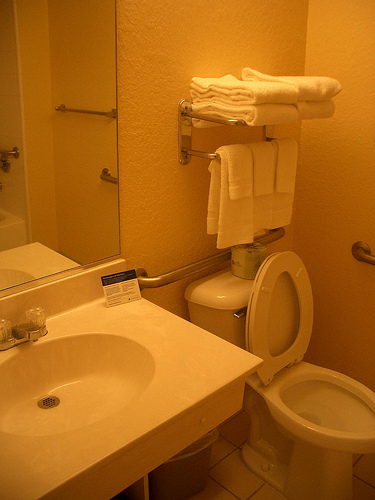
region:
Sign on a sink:
[97, 266, 146, 310]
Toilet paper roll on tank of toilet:
[230, 241, 266, 279]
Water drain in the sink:
[35, 395, 60, 409]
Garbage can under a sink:
[149, 427, 224, 497]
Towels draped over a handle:
[205, 137, 297, 246]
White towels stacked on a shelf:
[190, 65, 339, 122]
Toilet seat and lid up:
[247, 248, 315, 381]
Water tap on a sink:
[0, 306, 50, 350]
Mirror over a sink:
[0, 0, 121, 289]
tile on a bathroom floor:
[184, 406, 370, 499]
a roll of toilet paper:
[224, 233, 262, 286]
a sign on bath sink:
[80, 258, 154, 316]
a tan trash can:
[155, 425, 226, 499]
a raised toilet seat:
[249, 250, 332, 410]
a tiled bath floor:
[187, 447, 262, 498]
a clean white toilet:
[190, 227, 372, 498]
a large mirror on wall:
[2, 0, 162, 270]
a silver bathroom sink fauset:
[0, 294, 77, 349]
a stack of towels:
[173, 49, 348, 141]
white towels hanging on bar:
[159, 140, 350, 253]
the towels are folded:
[200, 76, 358, 146]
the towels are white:
[198, 67, 344, 117]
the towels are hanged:
[215, 146, 300, 230]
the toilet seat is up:
[254, 260, 321, 371]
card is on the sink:
[97, 270, 142, 304]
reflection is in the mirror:
[5, 3, 123, 258]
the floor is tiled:
[218, 456, 239, 499]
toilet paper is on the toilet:
[229, 243, 269, 281]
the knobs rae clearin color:
[0, 303, 50, 338]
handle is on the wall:
[52, 99, 115, 123]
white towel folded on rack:
[181, 63, 288, 102]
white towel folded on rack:
[186, 96, 297, 119]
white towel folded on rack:
[292, 99, 344, 126]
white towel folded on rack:
[249, 64, 337, 102]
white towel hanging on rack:
[215, 139, 239, 241]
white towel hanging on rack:
[246, 140, 275, 236]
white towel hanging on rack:
[275, 134, 299, 228]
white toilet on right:
[231, 253, 374, 490]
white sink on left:
[23, 306, 239, 498]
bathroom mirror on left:
[1, 7, 129, 315]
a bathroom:
[5, 7, 370, 496]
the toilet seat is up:
[247, 247, 373, 453]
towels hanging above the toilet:
[205, 134, 306, 250]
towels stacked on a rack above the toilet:
[182, 62, 349, 140]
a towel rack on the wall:
[165, 59, 317, 249]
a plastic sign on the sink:
[95, 267, 148, 308]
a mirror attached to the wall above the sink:
[2, 1, 131, 275]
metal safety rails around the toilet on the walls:
[135, 217, 373, 308]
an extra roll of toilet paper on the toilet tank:
[224, 238, 269, 281]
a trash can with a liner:
[151, 428, 219, 498]